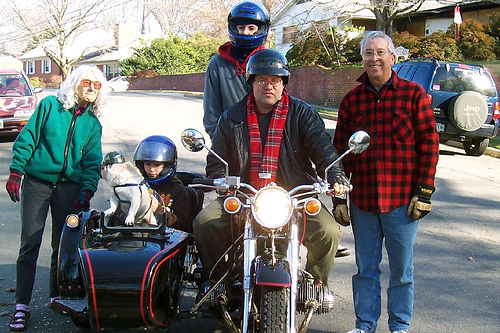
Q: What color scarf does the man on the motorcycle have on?
A: Red plaid.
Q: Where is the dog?
A: In sidecar.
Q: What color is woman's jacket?
A: Green.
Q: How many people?
A: Five.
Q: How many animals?
A: One.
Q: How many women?
A: One woman.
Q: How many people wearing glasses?
A: Three.